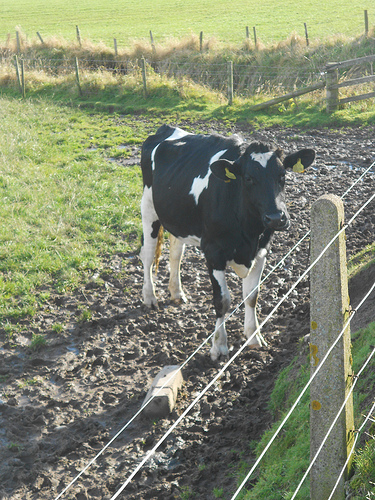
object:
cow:
[136, 122, 316, 361]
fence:
[1, 55, 375, 115]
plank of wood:
[140, 365, 188, 420]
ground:
[3, 2, 373, 500]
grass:
[3, 91, 81, 122]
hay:
[5, 40, 367, 71]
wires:
[15, 55, 374, 88]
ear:
[208, 156, 241, 183]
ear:
[282, 147, 316, 175]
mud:
[83, 302, 138, 428]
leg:
[245, 252, 266, 353]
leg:
[203, 243, 236, 360]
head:
[211, 141, 316, 233]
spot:
[249, 151, 277, 167]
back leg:
[137, 182, 160, 307]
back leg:
[167, 230, 185, 305]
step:
[82, 345, 111, 363]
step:
[142, 319, 159, 332]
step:
[319, 165, 331, 178]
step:
[290, 262, 300, 273]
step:
[101, 294, 117, 307]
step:
[203, 391, 222, 406]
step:
[101, 392, 120, 405]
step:
[177, 330, 190, 342]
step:
[87, 434, 104, 450]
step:
[55, 392, 71, 410]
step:
[340, 159, 349, 169]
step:
[78, 319, 92, 330]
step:
[47, 364, 60, 378]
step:
[132, 433, 170, 454]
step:
[131, 271, 143, 284]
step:
[295, 191, 306, 200]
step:
[239, 352, 268, 365]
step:
[41, 432, 62, 447]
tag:
[222, 167, 239, 182]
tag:
[292, 160, 308, 173]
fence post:
[139, 57, 154, 99]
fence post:
[306, 193, 359, 499]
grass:
[55, 257, 75, 283]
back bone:
[155, 124, 244, 151]